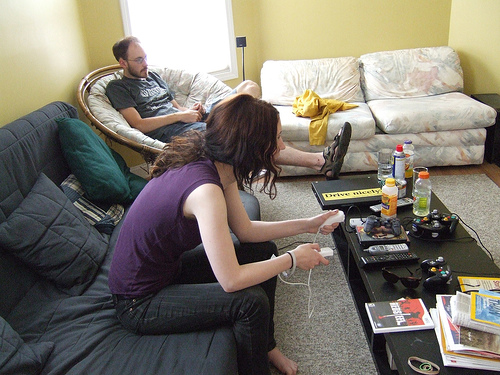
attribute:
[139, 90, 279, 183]
hair — brown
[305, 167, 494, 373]
table — black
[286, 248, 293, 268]
black band — white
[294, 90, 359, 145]
shirt — yellow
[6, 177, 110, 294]
throw pillow — multiple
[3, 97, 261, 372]
couch — blue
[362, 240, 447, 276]
remote control — black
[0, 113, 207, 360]
couch — gray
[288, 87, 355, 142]
clothing — yellow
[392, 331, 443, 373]
bands — rubber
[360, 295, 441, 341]
case — red, black